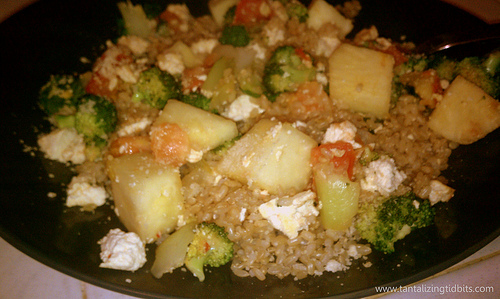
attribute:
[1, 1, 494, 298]
plate — black